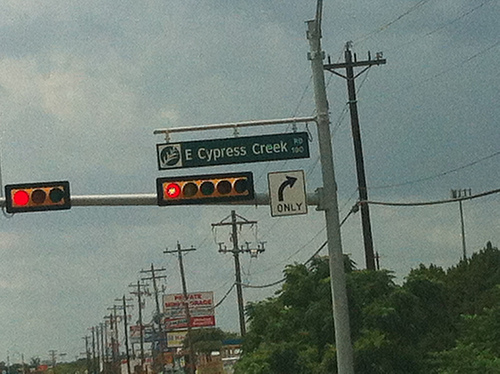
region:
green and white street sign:
[146, 125, 320, 169]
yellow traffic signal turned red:
[152, 171, 261, 199]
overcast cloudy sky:
[28, 33, 228, 120]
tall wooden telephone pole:
[212, 210, 255, 365]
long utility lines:
[366, 133, 498, 245]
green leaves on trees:
[248, 280, 325, 348]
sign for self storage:
[152, 282, 221, 352]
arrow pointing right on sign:
[263, 163, 308, 225]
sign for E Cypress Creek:
[177, 140, 294, 160]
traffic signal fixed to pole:
[5, 171, 75, 222]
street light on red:
[162, 175, 249, 200]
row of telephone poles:
[89, 203, 267, 370]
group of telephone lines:
[354, 22, 487, 199]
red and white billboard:
[159, 287, 222, 330]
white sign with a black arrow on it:
[268, 170, 310, 215]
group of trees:
[259, 255, 496, 362]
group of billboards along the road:
[124, 294, 212, 364]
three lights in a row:
[4, 182, 74, 215]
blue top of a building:
[222, 336, 246, 346]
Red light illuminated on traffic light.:
[153, 175, 200, 219]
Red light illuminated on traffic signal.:
[17, 177, 56, 243]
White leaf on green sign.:
[151, 136, 193, 174]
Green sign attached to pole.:
[157, 128, 317, 170]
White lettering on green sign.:
[178, 144, 308, 161]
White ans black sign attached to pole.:
[266, 175, 318, 226]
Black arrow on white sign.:
[266, 163, 327, 233]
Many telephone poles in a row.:
[70, 272, 311, 347]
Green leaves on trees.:
[297, 281, 438, 359]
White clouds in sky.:
[23, 44, 116, 156]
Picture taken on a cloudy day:
[3, 3, 464, 317]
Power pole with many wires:
[298, 25, 495, 240]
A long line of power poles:
[50, 214, 262, 345]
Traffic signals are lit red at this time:
[3, 149, 267, 214]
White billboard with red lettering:
[138, 288, 242, 340]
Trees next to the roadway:
[254, 257, 486, 363]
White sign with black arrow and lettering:
[258, 154, 314, 227]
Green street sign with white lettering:
[148, 122, 318, 160]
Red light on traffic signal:
[157, 176, 190, 201]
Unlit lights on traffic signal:
[180, 167, 250, 206]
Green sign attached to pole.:
[153, 140, 338, 157]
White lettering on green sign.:
[158, 137, 310, 170]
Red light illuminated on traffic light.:
[154, 163, 231, 262]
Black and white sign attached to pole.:
[261, 160, 332, 256]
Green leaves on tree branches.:
[212, 258, 498, 355]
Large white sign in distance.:
[159, 281, 247, 371]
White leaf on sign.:
[150, 133, 189, 180]